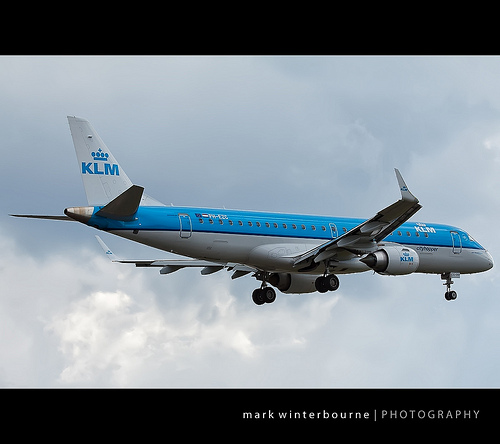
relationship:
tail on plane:
[65, 111, 171, 210] [7, 113, 497, 310]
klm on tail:
[79, 159, 122, 179] [65, 111, 171, 210]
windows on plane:
[195, 214, 431, 240] [7, 113, 497, 310]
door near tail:
[174, 210, 194, 243] [65, 111, 171, 210]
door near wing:
[327, 220, 342, 240] [289, 161, 424, 273]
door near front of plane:
[450, 228, 466, 257] [418, 216, 499, 304]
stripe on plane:
[102, 222, 487, 253] [7, 113, 497, 310]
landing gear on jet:
[248, 263, 463, 309] [7, 113, 497, 310]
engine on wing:
[360, 242, 420, 278] [289, 161, 424, 273]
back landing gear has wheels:
[249, 257, 343, 307] [252, 272, 339, 305]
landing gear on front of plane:
[440, 270, 461, 302] [418, 216, 499, 304]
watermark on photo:
[240, 404, 371, 424] [2, 1, 500, 442]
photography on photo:
[380, 404, 480, 421] [2, 1, 500, 442]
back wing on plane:
[92, 180, 146, 221] [7, 113, 497, 310]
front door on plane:
[450, 228, 466, 257] [7, 113, 497, 310]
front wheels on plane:
[442, 288, 458, 301] [7, 113, 497, 310]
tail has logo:
[65, 111, 171, 210] [79, 142, 122, 177]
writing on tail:
[79, 159, 122, 179] [65, 111, 171, 210]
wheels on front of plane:
[442, 288, 458, 301] [418, 216, 499, 304]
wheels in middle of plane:
[252, 272, 339, 305] [172, 158, 421, 313]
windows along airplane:
[195, 214, 431, 240] [7, 113, 497, 310]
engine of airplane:
[360, 242, 420, 278] [7, 113, 497, 310]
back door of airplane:
[174, 210, 194, 243] [7, 113, 497, 310]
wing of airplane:
[289, 161, 424, 273] [7, 113, 497, 310]